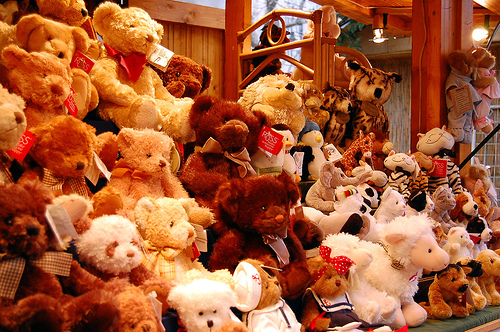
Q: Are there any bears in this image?
A: Yes, there is a bear.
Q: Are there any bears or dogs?
A: Yes, there is a bear.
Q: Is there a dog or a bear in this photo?
A: Yes, there is a bear.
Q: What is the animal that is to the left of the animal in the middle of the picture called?
A: The animal is a bear.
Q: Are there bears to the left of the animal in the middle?
A: Yes, there is a bear to the left of the animal.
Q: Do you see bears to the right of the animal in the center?
A: No, the bear is to the left of the animal.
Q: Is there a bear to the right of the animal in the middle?
A: No, the bear is to the left of the animal.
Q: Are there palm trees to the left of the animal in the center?
A: No, there is a bear to the left of the animal.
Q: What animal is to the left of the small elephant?
A: The animal is a bear.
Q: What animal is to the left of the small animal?
A: The animal is a bear.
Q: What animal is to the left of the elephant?
A: The animal is a bear.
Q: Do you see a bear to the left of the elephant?
A: Yes, there is a bear to the left of the elephant.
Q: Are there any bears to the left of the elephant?
A: Yes, there is a bear to the left of the elephant.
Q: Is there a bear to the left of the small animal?
A: Yes, there is a bear to the left of the elephant.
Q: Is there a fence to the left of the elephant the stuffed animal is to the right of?
A: No, there is a bear to the left of the elephant.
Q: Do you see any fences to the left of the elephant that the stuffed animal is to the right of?
A: No, there is a bear to the left of the elephant.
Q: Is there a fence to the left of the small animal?
A: No, there is a bear to the left of the elephant.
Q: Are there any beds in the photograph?
A: No, there are no beds.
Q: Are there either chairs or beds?
A: No, there are no beds or chairs.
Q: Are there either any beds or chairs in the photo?
A: No, there are no beds or chairs.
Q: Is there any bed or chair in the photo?
A: No, there are no beds or chairs.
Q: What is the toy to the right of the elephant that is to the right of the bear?
A: The toy is a stuffed animal.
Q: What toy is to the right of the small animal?
A: The toy is a stuffed animal.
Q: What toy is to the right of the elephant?
A: The toy is a stuffed animal.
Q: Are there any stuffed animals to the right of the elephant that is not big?
A: Yes, there is a stuffed animal to the right of the elephant.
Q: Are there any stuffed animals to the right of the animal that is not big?
A: Yes, there is a stuffed animal to the right of the elephant.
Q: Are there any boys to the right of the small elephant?
A: No, there is a stuffed animal to the right of the elephant.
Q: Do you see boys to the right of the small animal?
A: No, there is a stuffed animal to the right of the elephant.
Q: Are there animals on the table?
A: Yes, there is an animal on the table.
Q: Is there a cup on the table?
A: No, there is an animal on the table.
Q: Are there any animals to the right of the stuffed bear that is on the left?
A: Yes, there is an animal to the right of the stuffed bear.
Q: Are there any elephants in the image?
A: Yes, there is an elephant.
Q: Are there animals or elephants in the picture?
A: Yes, there is an elephant.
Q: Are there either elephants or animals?
A: Yes, there is an elephant.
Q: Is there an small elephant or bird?
A: Yes, there is a small elephant.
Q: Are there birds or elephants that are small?
A: Yes, the elephant is small.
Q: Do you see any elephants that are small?
A: Yes, there is a small elephant.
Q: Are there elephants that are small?
A: Yes, there is an elephant that is small.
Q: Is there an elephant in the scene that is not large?
A: Yes, there is a small elephant.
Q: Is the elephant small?
A: Yes, the elephant is small.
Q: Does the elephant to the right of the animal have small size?
A: Yes, the elephant is small.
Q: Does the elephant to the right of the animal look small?
A: Yes, the elephant is small.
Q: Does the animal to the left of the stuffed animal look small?
A: Yes, the elephant is small.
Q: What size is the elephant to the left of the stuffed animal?
A: The elephant is small.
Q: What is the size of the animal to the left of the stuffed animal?
A: The elephant is small.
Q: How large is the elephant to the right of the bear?
A: The elephant is small.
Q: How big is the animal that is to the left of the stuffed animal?
A: The elephant is small.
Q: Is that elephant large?
A: No, the elephant is small.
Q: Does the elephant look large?
A: No, the elephant is small.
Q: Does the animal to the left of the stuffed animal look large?
A: No, the elephant is small.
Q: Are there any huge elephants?
A: No, there is an elephant but it is small.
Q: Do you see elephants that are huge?
A: No, there is an elephant but it is small.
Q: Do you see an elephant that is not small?
A: No, there is an elephant but it is small.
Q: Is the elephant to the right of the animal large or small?
A: The elephant is small.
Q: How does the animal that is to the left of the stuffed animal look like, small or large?
A: The elephant is small.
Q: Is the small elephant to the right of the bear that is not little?
A: Yes, the elephant is to the right of the bear.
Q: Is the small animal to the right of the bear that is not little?
A: Yes, the elephant is to the right of the bear.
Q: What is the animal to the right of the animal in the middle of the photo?
A: The animal is an elephant.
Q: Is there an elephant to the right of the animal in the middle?
A: Yes, there is an elephant to the right of the animal.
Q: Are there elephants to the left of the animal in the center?
A: No, the elephant is to the right of the animal.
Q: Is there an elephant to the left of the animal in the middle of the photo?
A: No, the elephant is to the right of the animal.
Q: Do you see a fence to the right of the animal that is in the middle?
A: No, there is an elephant to the right of the animal.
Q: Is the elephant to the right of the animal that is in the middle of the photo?
A: Yes, the elephant is to the right of the animal.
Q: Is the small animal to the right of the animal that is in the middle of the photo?
A: Yes, the elephant is to the right of the animal.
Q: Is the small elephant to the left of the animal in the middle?
A: No, the elephant is to the right of the animal.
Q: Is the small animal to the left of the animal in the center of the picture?
A: No, the elephant is to the right of the animal.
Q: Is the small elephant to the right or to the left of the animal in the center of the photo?
A: The elephant is to the right of the animal.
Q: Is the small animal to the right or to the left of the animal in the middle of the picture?
A: The elephant is to the right of the animal.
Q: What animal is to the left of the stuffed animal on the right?
A: The animal is an elephant.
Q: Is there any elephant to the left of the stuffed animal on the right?
A: Yes, there is an elephant to the left of the stuffed animal.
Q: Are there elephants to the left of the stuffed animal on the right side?
A: Yes, there is an elephant to the left of the stuffed animal.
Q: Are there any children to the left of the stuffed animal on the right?
A: No, there is an elephant to the left of the stuffed animal.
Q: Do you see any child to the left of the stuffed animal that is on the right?
A: No, there is an elephant to the left of the stuffed animal.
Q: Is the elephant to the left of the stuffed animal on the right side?
A: Yes, the elephant is to the left of the stuffed animal.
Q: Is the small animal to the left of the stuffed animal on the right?
A: Yes, the elephant is to the left of the stuffed animal.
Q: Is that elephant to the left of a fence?
A: No, the elephant is to the left of the stuffed animal.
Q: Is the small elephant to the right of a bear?
A: Yes, the elephant is to the right of a bear.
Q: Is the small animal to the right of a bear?
A: Yes, the elephant is to the right of a bear.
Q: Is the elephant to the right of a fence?
A: No, the elephant is to the right of a bear.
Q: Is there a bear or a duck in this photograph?
A: Yes, there is a bear.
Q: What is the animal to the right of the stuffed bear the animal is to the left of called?
A: The animal is a bear.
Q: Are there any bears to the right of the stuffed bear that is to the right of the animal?
A: Yes, there is a bear to the right of the stuffed bear.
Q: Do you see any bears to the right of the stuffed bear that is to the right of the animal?
A: Yes, there is a bear to the right of the stuffed bear.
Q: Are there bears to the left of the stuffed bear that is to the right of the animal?
A: No, the bear is to the right of the stuffed bear.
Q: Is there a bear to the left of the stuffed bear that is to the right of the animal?
A: No, the bear is to the right of the stuffed bear.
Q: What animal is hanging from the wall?
A: The bear is hanging from the wall.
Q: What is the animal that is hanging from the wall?
A: The animal is a bear.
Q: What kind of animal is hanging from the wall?
A: The animal is a bear.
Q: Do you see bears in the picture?
A: Yes, there is a bear.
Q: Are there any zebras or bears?
A: Yes, there is a bear.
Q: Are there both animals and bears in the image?
A: Yes, there are both a bear and an animal.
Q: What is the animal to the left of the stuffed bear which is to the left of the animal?
A: The animal is a bear.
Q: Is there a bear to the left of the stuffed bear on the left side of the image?
A: Yes, there is a bear to the left of the stuffed bear.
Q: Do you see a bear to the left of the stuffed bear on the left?
A: Yes, there is a bear to the left of the stuffed bear.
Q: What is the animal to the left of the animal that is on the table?
A: The animal is a bear.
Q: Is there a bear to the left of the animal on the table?
A: Yes, there is a bear to the left of the animal.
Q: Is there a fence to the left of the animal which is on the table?
A: No, there is a bear to the left of the animal.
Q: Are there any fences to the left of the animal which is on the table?
A: No, there is a bear to the left of the animal.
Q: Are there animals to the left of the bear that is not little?
A: No, the animal is to the right of the bear.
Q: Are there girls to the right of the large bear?
A: No, there is an animal to the right of the bear.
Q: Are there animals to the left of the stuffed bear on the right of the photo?
A: Yes, there is an animal to the left of the stuffed bear.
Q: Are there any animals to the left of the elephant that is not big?
A: Yes, there is an animal to the left of the elephant.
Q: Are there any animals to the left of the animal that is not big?
A: Yes, there is an animal to the left of the elephant.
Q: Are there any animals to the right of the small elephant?
A: No, the animal is to the left of the elephant.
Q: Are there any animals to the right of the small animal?
A: No, the animal is to the left of the elephant.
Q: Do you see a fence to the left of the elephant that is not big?
A: No, there is an animal to the left of the elephant.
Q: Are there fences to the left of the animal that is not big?
A: No, there is an animal to the left of the elephant.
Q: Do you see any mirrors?
A: No, there are no mirrors.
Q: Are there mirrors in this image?
A: No, there are no mirrors.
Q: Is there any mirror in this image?
A: No, there are no mirrors.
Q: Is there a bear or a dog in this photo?
A: Yes, there is a bear.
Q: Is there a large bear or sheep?
A: Yes, there is a large bear.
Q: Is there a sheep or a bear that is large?
A: Yes, the bear is large.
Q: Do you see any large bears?
A: Yes, there is a large bear.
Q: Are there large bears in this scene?
A: Yes, there is a large bear.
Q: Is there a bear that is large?
A: Yes, there is a bear that is large.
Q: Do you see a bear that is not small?
A: Yes, there is a large bear.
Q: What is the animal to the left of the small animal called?
A: The animal is a bear.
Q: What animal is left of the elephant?
A: The animal is a bear.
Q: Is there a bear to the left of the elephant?
A: Yes, there is a bear to the left of the elephant.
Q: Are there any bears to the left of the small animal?
A: Yes, there is a bear to the left of the elephant.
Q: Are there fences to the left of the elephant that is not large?
A: No, there is a bear to the left of the elephant.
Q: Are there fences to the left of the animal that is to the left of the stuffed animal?
A: No, there is a bear to the left of the elephant.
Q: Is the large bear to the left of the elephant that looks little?
A: Yes, the bear is to the left of the elephant.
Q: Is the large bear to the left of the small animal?
A: Yes, the bear is to the left of the elephant.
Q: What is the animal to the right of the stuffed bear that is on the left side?
A: The animal is a bear.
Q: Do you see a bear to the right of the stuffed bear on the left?
A: Yes, there is a bear to the right of the stuffed bear.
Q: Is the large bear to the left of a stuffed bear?
A: No, the bear is to the right of a stuffed bear.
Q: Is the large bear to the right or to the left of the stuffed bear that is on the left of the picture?
A: The bear is to the right of the stuffed bear.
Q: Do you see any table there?
A: Yes, there is a table.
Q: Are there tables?
A: Yes, there is a table.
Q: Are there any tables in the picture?
A: Yes, there is a table.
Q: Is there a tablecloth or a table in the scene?
A: Yes, there is a table.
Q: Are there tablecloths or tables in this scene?
A: Yes, there is a table.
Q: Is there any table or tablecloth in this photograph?
A: Yes, there is a table.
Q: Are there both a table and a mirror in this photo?
A: No, there is a table but no mirrors.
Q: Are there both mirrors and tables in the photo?
A: No, there is a table but no mirrors.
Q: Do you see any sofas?
A: No, there are no sofas.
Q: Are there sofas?
A: No, there are no sofas.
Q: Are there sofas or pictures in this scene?
A: No, there are no sofas or pictures.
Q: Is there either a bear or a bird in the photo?
A: Yes, there is a bear.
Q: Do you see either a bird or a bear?
A: Yes, there is a bear.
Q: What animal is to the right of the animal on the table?
A: The animal is a bear.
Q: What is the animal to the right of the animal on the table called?
A: The animal is a bear.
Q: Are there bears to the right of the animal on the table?
A: Yes, there is a bear to the right of the animal.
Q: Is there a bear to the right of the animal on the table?
A: Yes, there is a bear to the right of the animal.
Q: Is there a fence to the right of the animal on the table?
A: No, there is a bear to the right of the animal.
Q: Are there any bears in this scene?
A: Yes, there is a bear.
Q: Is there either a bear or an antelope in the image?
A: Yes, there is a bear.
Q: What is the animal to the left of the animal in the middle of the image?
A: The animal is a bear.